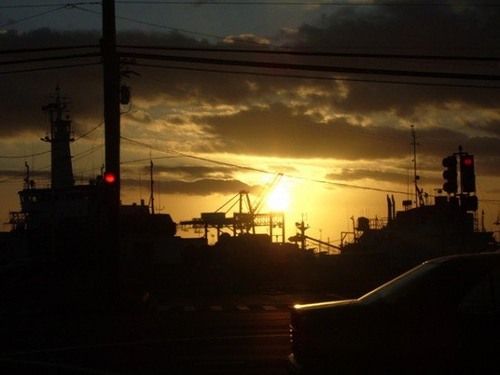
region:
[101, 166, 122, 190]
red light on a traffic signal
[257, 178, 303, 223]
bright sun getting ready to set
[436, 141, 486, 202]
traffic lights above a street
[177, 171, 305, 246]
construction materials in the distance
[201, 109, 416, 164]
clouds in the sky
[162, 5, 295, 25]
dark blue sky in the distance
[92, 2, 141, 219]
telephone pole connecting wires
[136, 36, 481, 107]
electrical wires in the air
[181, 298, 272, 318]
white lines painted on street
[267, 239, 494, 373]
car on the street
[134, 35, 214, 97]
clouds in sky at sunset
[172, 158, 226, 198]
clouds in sky at sunset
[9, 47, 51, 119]
clouds in sky at sunset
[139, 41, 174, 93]
clouds in sky at sunset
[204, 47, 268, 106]
clouds in sky at sunset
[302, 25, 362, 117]
clouds in sky at sunset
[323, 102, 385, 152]
clouds in sky at sunset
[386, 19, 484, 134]
clouds in sky at sunset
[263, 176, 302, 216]
sun in sky at sunset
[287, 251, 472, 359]
car on road at sunset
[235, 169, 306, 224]
Sun is shining brightly.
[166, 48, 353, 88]
Clouds are grey color.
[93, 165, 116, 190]
Red light is on.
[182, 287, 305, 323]
Black and white lines in road.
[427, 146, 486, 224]
Signal light is on.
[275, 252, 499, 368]
Car is on road.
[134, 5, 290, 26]
Sky is grey color.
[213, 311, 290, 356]
Road is grey color.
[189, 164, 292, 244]
Crane is behind the car.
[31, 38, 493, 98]
Wire lines are passing above the road.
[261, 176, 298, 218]
Sun in the sky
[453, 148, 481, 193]
Red street light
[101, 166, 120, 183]
A red light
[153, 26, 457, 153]
Clouds in the sky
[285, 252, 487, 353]
A car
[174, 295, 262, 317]
A cross walk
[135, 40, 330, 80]
Power lines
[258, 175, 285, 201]
A craine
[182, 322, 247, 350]
The car is on the street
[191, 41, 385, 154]
Clouds in the sky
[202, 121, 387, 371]
the sun is bright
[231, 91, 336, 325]
the sun is bright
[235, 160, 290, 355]
the sun is bright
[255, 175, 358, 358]
the sun is bright